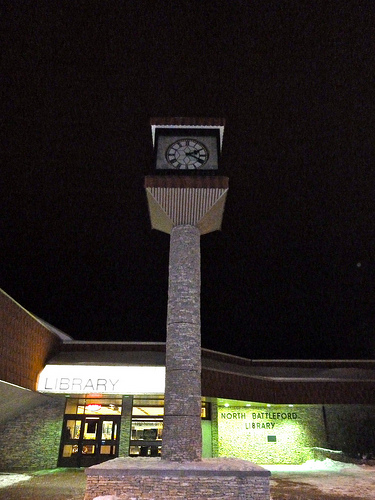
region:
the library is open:
[39, 342, 202, 487]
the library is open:
[66, 363, 151, 490]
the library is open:
[0, 326, 181, 441]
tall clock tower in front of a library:
[34, 107, 231, 494]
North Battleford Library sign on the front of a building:
[210, 391, 319, 447]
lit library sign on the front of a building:
[34, 357, 148, 395]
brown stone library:
[1, 294, 372, 496]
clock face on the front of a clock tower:
[162, 129, 218, 176]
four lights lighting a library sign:
[213, 396, 318, 443]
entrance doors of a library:
[45, 363, 122, 476]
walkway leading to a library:
[9, 444, 87, 498]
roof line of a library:
[6, 299, 372, 395]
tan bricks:
[87, 466, 271, 497]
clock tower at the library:
[139, 115, 237, 456]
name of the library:
[216, 406, 304, 430]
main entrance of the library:
[51, 410, 123, 478]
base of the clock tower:
[78, 454, 275, 499]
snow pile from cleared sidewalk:
[272, 455, 374, 490]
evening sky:
[257, 163, 374, 326]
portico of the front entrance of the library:
[201, 345, 370, 412]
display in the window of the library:
[141, 425, 162, 441]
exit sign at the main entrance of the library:
[77, 397, 107, 406]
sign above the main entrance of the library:
[35, 362, 165, 396]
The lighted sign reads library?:
[40, 368, 141, 402]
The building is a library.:
[27, 289, 353, 485]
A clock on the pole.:
[144, 95, 226, 187]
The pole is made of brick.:
[159, 299, 254, 498]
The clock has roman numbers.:
[158, 125, 210, 178]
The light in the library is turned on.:
[82, 396, 115, 417]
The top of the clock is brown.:
[146, 105, 231, 133]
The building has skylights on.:
[208, 396, 311, 414]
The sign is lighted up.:
[42, 367, 114, 400]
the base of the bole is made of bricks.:
[84, 448, 280, 497]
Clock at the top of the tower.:
[150, 120, 223, 177]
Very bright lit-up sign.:
[35, 363, 163, 394]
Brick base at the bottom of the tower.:
[84, 454, 274, 499]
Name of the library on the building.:
[219, 408, 303, 432]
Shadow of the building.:
[4, 464, 349, 498]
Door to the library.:
[58, 397, 163, 463]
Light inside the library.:
[83, 401, 105, 412]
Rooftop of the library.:
[3, 288, 369, 402]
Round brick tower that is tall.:
[161, 222, 202, 464]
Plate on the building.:
[264, 433, 279, 444]